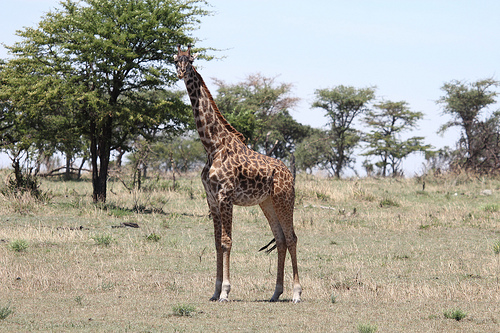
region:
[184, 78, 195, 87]
brown spot on giraffe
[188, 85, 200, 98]
brown spot on giraffe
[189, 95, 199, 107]
brown spot on giraffe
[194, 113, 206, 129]
brown spot on giraffe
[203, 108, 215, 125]
brown spot on giraffe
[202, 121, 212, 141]
brown spot on giraffe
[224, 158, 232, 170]
brown spot on giraffe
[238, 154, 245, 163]
brown spot on giraffe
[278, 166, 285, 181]
brown spot on giraffe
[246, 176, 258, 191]
brown spot on giraffe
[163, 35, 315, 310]
a big giraffe in field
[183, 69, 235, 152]
long neck of giraffe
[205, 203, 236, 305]
front legs of giraffe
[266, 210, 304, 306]
back legs of giraffe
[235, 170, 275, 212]
bulky belly of giraffe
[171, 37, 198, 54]
two horns of giraffe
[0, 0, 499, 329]
trees on the field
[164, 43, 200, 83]
head of giraffe is small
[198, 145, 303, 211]
big body of giraffe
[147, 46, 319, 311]
a fully grown adult giraffe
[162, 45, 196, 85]
the face of an adult giraffe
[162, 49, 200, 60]
the ears of an adult giraffe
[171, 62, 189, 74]
the mouth of an adult giraffe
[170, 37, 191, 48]
the horns of an adult giraffe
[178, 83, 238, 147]
the neck of an adult giraffe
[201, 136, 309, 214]
the body of an adult giraffe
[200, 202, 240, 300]
the front legs of an adult giraffe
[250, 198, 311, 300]
the back legs of an adult giraffe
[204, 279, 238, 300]
the hooves of an adult giraffe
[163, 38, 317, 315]
A giraffe in a grassy field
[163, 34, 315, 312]
A giraffe in a grassy field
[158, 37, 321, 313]
A giraffe in a grassy field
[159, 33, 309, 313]
A giraffe in a grassy field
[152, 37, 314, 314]
A giraffe in a grassy field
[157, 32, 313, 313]
A giraffe in a grassy field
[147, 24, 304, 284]
brown spotted giraffe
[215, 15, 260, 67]
white clouds in blue sky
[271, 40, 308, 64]
white clouds in blue sky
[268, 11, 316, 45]
white clouds in blue sky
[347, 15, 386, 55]
white clouds in blue sky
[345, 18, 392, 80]
white clouds in blue sky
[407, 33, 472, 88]
white clouds in blue sky